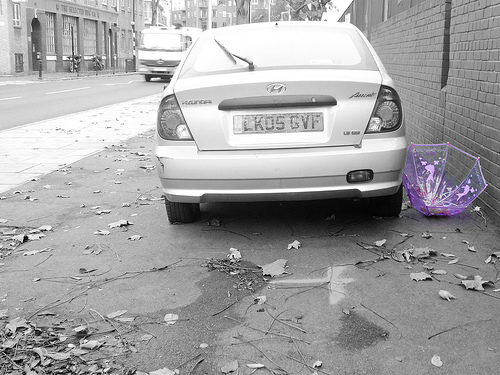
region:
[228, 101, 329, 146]
Black and white license plate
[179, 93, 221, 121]
Silver Hyundai car logo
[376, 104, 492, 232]
Pink and purple umbrella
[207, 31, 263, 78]
Black wiper blade on car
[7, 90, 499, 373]
Black and white leaves on ground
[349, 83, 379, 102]
Silver 'Accent' sign on back of car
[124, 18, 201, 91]
Black and white truck coming down the road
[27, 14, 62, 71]
Small archway in building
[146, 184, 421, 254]
Two black back tires on car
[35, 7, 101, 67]
Three large square windows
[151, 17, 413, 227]
White car with two tail lights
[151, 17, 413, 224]
White car with wind shield wipers on back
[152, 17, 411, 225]
White car with trunk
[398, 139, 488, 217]
Purple umbrella with spokes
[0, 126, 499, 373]
Purple umbrella on ground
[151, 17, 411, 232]
White car with back window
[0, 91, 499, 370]
Leaves on parking lot ground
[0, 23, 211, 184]
Truck coming down street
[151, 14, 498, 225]
Brick wall next to car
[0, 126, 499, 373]
Oil spots on ground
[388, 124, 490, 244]
The umbrella is lying on the ground.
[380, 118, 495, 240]
The umbrella is open.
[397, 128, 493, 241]
The umbrella has a purplish tint to it.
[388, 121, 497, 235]
The umbrella has pink designs on it.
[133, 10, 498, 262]
The car is parked next to a brick wall.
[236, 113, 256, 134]
The letter is black.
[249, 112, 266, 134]
The letter is black.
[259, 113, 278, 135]
The letter is black.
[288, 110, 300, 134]
The letter is black.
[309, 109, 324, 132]
The letter is black.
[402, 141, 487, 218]
purple umbrella upside down on ground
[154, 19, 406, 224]
light colored sedan parked on road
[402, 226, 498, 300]
dead leaves on ground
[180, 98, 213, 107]
hyundai logo on trunk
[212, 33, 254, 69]
rear windshield wiper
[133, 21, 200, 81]
truck driving down road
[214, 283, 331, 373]
twigs scattered on pavement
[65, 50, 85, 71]
bike parked on sidewalk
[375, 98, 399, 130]
round clear tail light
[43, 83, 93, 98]
white stripe painted in center of road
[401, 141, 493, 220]
a transparent umbrella with fish and star design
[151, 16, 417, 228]
a light colored sedan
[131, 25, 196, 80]
a bus with sun on windshield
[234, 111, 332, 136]
licence plate of the car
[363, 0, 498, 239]
the brick wall of the building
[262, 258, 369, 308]
a white spray painted marking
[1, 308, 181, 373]
a pile of fallen fall leaves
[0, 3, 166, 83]
an older building with several arches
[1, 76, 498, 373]
a concrete pavement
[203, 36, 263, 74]
a windshield wiper